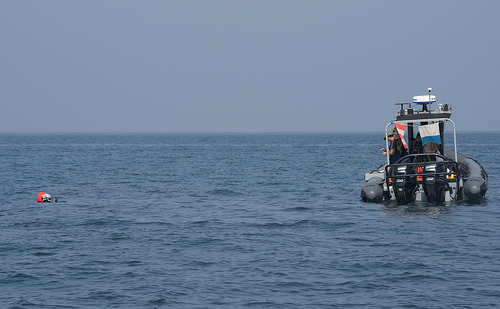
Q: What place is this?
A: It is an ocean.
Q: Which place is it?
A: It is an ocean.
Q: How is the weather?
A: It is clear.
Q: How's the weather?
A: It is clear.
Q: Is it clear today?
A: Yes, it is clear.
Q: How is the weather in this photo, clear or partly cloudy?
A: It is clear.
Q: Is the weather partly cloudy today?
A: No, it is clear.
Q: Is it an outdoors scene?
A: Yes, it is outdoors.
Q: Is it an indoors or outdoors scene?
A: It is outdoors.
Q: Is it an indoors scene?
A: No, it is outdoors.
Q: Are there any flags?
A: Yes, there is a flag.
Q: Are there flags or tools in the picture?
A: Yes, there is a flag.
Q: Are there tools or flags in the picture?
A: Yes, there is a flag.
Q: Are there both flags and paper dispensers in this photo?
A: No, there is a flag but no paper dispensers.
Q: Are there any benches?
A: No, there are no benches.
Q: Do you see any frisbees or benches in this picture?
A: No, there are no benches or frisbees.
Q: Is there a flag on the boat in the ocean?
A: Yes, there is a flag on the boat.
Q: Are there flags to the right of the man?
A: Yes, there is a flag to the right of the man.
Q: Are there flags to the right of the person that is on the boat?
A: Yes, there is a flag to the right of the man.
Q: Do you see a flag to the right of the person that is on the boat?
A: Yes, there is a flag to the right of the man.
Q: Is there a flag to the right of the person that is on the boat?
A: Yes, there is a flag to the right of the man.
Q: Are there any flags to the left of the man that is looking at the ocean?
A: No, the flag is to the right of the man.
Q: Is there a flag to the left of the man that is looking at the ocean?
A: No, the flag is to the right of the man.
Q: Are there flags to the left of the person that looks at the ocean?
A: No, the flag is to the right of the man.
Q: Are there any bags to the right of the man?
A: No, there is a flag to the right of the man.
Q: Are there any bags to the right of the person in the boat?
A: No, there is a flag to the right of the man.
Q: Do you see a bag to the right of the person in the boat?
A: No, there is a flag to the right of the man.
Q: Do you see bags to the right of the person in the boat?
A: No, there is a flag to the right of the man.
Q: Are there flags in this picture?
A: Yes, there is a flag.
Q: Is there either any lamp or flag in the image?
A: Yes, there is a flag.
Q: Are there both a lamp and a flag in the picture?
A: No, there is a flag but no lamps.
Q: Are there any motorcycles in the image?
A: No, there are no motorcycles.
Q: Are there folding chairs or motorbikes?
A: No, there are no motorbikes or folding chairs.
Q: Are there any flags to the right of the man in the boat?
A: Yes, there is a flag to the right of the man.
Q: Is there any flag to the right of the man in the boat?
A: Yes, there is a flag to the right of the man.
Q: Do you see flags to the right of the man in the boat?
A: Yes, there is a flag to the right of the man.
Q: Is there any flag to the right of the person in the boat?
A: Yes, there is a flag to the right of the man.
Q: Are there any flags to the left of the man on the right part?
A: No, the flag is to the right of the man.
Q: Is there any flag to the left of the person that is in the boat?
A: No, the flag is to the right of the man.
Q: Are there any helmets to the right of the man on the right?
A: No, there is a flag to the right of the man.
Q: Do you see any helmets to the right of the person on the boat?
A: No, there is a flag to the right of the man.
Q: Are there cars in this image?
A: No, there are no cars.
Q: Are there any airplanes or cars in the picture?
A: No, there are no cars or airplanes.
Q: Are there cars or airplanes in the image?
A: No, there are no cars or airplanes.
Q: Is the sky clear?
A: Yes, the sky is clear.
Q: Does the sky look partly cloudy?
A: No, the sky is clear.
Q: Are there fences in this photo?
A: No, there are no fences.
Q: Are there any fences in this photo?
A: No, there are no fences.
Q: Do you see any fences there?
A: No, there are no fences.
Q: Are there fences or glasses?
A: No, there are no fences or glasses.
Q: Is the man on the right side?
A: Yes, the man is on the right of the image.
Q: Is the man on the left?
A: No, the man is on the right of the image.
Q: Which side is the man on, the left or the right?
A: The man is on the right of the image.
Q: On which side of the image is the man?
A: The man is on the right of the image.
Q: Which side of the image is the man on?
A: The man is on the right of the image.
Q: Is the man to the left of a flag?
A: Yes, the man is to the left of a flag.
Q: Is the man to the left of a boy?
A: No, the man is to the left of a flag.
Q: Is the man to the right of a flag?
A: No, the man is to the left of a flag.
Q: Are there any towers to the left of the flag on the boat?
A: No, there is a man to the left of the flag.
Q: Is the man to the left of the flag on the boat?
A: Yes, the man is to the left of the flag.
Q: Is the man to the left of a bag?
A: No, the man is to the left of the flag.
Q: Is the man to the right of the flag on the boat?
A: No, the man is to the left of the flag.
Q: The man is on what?
A: The man is on the boat.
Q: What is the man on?
A: The man is on the boat.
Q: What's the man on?
A: The man is on the boat.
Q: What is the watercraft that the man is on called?
A: The watercraft is a boat.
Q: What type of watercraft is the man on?
A: The man is on the boat.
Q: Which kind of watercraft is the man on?
A: The man is on the boat.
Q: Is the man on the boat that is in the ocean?
A: Yes, the man is on the boat.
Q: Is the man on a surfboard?
A: No, the man is on the boat.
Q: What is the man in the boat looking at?
A: The man is looking at the ocean.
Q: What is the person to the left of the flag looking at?
A: The man is looking at the ocean.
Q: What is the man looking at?
A: The man is looking at the ocean.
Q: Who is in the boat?
A: The man is in the boat.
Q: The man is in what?
A: The man is in the boat.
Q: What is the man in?
A: The man is in the boat.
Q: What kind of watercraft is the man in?
A: The man is in the boat.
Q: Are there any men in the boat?
A: Yes, there is a man in the boat.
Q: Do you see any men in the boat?
A: Yes, there is a man in the boat.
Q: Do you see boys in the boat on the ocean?
A: No, there is a man in the boat.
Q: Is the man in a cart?
A: No, the man is in the boat.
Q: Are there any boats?
A: Yes, there is a boat.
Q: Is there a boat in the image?
A: Yes, there is a boat.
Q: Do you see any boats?
A: Yes, there is a boat.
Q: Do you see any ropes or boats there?
A: Yes, there is a boat.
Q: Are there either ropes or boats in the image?
A: Yes, there is a boat.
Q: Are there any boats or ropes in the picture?
A: Yes, there is a boat.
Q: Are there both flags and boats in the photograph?
A: Yes, there are both a boat and a flag.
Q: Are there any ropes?
A: No, there are no ropes.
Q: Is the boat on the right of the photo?
A: Yes, the boat is on the right of the image.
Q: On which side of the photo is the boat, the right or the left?
A: The boat is on the right of the image.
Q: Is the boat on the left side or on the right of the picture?
A: The boat is on the right of the image.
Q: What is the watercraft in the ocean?
A: The watercraft is a boat.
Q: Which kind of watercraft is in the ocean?
A: The watercraft is a boat.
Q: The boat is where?
A: The boat is in the ocean.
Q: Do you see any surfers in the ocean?
A: No, there is a boat in the ocean.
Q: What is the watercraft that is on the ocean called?
A: The watercraft is a boat.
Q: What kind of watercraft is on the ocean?
A: The watercraft is a boat.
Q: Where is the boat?
A: The boat is on the ocean.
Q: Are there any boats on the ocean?
A: Yes, there is a boat on the ocean.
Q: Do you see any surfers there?
A: No, there are no surfers.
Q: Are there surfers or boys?
A: No, there are no surfers or boys.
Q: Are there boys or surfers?
A: No, there are no surfers or boys.